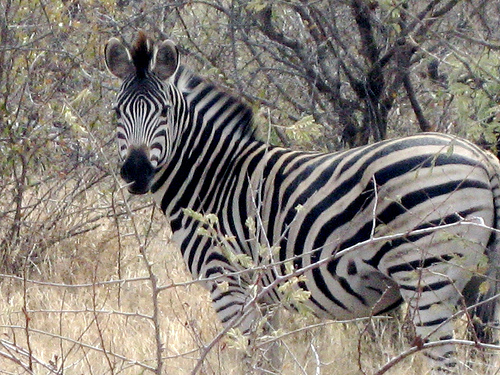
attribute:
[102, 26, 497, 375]
zebra — black, white, animal, horse-like, alone, eating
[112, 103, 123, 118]
eye — black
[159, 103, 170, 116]
eye — black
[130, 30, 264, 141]
mane — striped, black, white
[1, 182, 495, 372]
grass — brown, dry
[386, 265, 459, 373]
leg — rear, black, striped, white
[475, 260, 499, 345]
leg — rear, black, striped, white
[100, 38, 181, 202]
head — black, striped, white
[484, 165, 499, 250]
tail — black, striped, white, fluffy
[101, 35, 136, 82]
ear — black, large, white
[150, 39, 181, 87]
ear — black, large, white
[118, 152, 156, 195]
snout — black